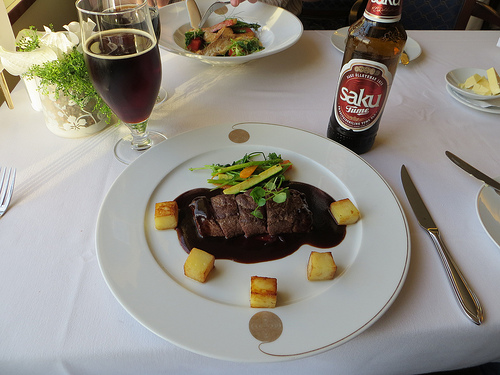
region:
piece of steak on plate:
[195, 186, 331, 226]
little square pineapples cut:
[182, 248, 363, 307]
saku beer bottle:
[333, 13, 418, 168]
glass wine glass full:
[81, 25, 167, 153]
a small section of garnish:
[225, 158, 293, 197]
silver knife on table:
[397, 155, 482, 334]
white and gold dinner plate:
[114, 138, 403, 371]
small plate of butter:
[444, 59, 490, 124]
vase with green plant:
[38, 36, 97, 133]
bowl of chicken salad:
[170, 13, 299, 71]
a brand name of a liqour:
[336, 57, 386, 135]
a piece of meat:
[178, 252, 220, 280]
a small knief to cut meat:
[393, 160, 489, 332]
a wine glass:
[68, 0, 178, 153]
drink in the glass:
[97, 35, 166, 117]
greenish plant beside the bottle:
[28, 41, 113, 144]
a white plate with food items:
[198, 6, 301, 63]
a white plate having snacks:
[451, 59, 498, 97]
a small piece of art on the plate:
[252, 315, 296, 355]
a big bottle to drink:
[326, 4, 411, 151]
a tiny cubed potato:
[152, 200, 178, 231]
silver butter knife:
[397, 162, 484, 327]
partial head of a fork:
[0, 164, 19, 221]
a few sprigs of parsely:
[247, 173, 292, 221]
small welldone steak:
[187, 184, 312, 241]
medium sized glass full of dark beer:
[72, 0, 163, 167]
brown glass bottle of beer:
[324, 0, 409, 155]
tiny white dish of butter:
[443, 64, 498, 102]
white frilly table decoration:
[0, 15, 114, 140]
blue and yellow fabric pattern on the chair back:
[401, 0, 467, 32]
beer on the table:
[322, 0, 400, 156]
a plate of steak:
[119, 119, 386, 346]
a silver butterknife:
[385, 161, 499, 329]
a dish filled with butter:
[441, 55, 498, 111]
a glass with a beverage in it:
[70, 2, 177, 154]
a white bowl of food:
[149, 2, 315, 89]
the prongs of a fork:
[1, 162, 18, 214]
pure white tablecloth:
[10, 227, 90, 345]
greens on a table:
[21, 52, 136, 126]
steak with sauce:
[188, 185, 313, 240]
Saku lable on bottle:
[330, 64, 398, 132]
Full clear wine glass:
[73, 3, 173, 163]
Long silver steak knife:
[396, 161, 475, 338]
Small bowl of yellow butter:
[448, 64, 499, 111]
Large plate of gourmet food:
[118, 142, 403, 349]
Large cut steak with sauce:
[190, 188, 315, 243]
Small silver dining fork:
[0, 166, 23, 218]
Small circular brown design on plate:
[242, 306, 299, 348]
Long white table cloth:
[13, 273, 100, 350]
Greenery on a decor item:
[20, 35, 83, 134]